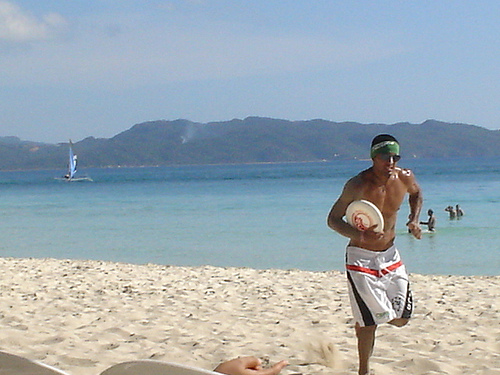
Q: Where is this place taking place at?
A: The beach.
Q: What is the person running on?
A: Sand.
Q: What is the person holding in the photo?
A: A frisbee.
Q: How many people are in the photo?
A: Six.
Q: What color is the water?
A: Blue.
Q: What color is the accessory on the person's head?
A: Green.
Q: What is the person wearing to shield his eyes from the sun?
A: Sunglasses.